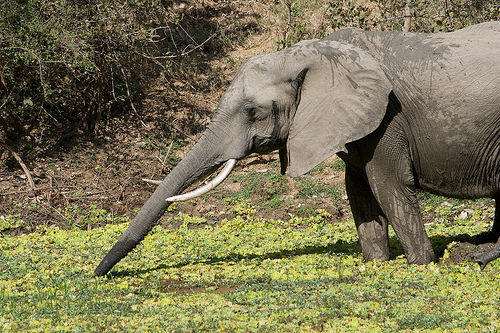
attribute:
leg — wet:
[359, 124, 427, 270]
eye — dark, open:
[241, 105, 258, 115]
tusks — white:
[132, 135, 240, 209]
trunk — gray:
[90, 142, 235, 278]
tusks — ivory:
[139, 143, 244, 212]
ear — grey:
[282, 44, 412, 174]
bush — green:
[8, 24, 225, 166]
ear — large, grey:
[278, 53, 395, 180]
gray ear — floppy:
[281, 35, 398, 182]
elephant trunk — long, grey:
[74, 85, 249, 280]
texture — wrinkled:
[393, 119, 423, 179]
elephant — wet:
[80, 9, 499, 279]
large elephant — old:
[91, 17, 499, 280]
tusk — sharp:
[139, 175, 165, 187]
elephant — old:
[267, 47, 495, 193]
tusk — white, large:
[166, 160, 236, 204]